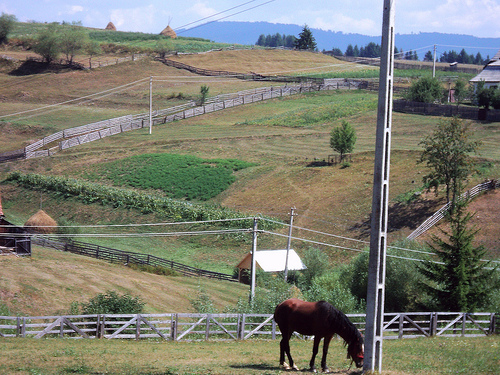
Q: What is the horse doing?
A: Grazing.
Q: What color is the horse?
A: Brown.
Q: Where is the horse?
A: Farm.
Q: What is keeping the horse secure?
A: Fence.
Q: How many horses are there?
A: One.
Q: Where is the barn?
A: Downhill.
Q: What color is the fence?
A: Gray.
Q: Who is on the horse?
A: No one.